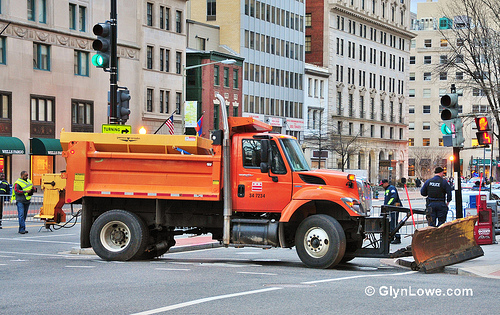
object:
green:
[91, 52, 108, 70]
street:
[0, 152, 497, 315]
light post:
[105, 86, 118, 127]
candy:
[415, 172, 455, 206]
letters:
[363, 285, 475, 302]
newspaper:
[462, 181, 487, 216]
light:
[439, 123, 454, 135]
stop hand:
[471, 112, 494, 146]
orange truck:
[54, 110, 471, 278]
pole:
[103, 0, 120, 127]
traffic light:
[93, 20, 113, 68]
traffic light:
[117, 84, 134, 121]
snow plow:
[405, 214, 484, 272]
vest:
[11, 179, 33, 201]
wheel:
[289, 210, 346, 267]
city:
[1, 3, 500, 313]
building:
[186, 50, 244, 137]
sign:
[128, 126, 156, 136]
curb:
[394, 249, 487, 283]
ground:
[0, 227, 500, 315]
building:
[240, 19, 307, 134]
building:
[297, 63, 336, 165]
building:
[235, 2, 306, 171]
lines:
[124, 268, 421, 315]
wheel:
[294, 213, 363, 269]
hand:
[447, 128, 458, 141]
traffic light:
[438, 94, 464, 135]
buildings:
[0, 0, 238, 211]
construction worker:
[11, 169, 39, 234]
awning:
[1, 142, 25, 163]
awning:
[34, 136, 61, 158]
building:
[181, 0, 311, 152]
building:
[304, 0, 408, 176]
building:
[405, 0, 494, 190]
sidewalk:
[398, 229, 499, 277]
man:
[420, 166, 452, 228]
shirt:
[425, 177, 445, 198]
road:
[3, 194, 498, 311]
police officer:
[378, 179, 403, 244]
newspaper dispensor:
[469, 193, 497, 246]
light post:
[108, 0, 118, 68]